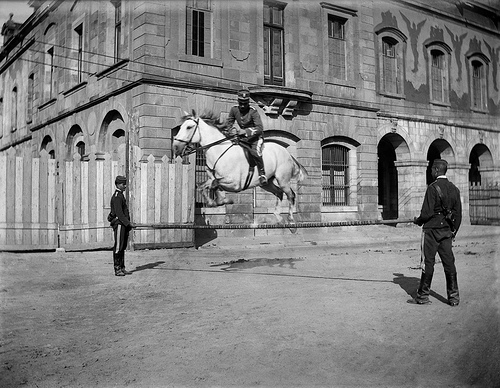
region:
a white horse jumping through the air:
[169, 107, 306, 233]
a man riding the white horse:
[212, 88, 267, 186]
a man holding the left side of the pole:
[107, 175, 133, 274]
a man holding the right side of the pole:
[407, 157, 464, 304]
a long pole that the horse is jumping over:
[121, 212, 416, 228]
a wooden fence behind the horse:
[0, 143, 196, 249]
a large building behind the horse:
[0, 0, 498, 255]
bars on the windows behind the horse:
[168, 121, 358, 212]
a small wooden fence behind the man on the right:
[469, 180, 499, 223]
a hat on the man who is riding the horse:
[238, 89, 250, 102]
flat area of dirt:
[17, 290, 277, 385]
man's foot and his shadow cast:
[380, 267, 445, 302]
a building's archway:
[366, 125, 412, 225]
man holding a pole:
[396, 155, 467, 307]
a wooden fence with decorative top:
[1, 131, 97, 256]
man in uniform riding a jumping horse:
[165, 81, 315, 217]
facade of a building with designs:
[347, 0, 492, 130]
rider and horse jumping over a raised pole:
[166, 80, 321, 272]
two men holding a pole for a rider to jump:
[96, 86, 466, 311]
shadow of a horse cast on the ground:
[207, 245, 312, 280]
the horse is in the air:
[159, 124, 308, 201]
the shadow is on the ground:
[226, 254, 291, 268]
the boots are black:
[414, 268, 461, 307]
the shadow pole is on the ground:
[166, 264, 388, 289]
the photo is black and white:
[5, 78, 497, 384]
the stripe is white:
[112, 224, 126, 249]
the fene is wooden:
[15, 155, 197, 250]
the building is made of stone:
[333, 95, 491, 150]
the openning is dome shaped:
[382, 136, 412, 215]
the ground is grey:
[133, 299, 365, 362]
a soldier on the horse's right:
[105, 171, 138, 276]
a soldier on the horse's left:
[390, 152, 472, 310]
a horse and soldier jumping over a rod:
[168, 74, 310, 225]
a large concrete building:
[4, 3, 493, 234]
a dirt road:
[0, 239, 497, 386]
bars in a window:
[322, 143, 356, 204]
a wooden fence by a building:
[4, 150, 202, 250]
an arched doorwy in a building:
[371, 124, 415, 229]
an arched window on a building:
[373, 25, 410, 101]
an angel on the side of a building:
[395, 10, 429, 79]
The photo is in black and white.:
[2, 0, 498, 385]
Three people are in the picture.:
[96, 80, 476, 325]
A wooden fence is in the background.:
[4, 154, 99, 252]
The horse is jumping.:
[163, 89, 322, 237]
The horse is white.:
[166, 74, 316, 230]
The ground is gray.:
[136, 289, 307, 369]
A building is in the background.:
[14, 0, 499, 225]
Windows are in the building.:
[361, 16, 498, 115]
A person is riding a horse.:
[168, 81, 315, 249]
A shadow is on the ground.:
[111, 239, 461, 322]